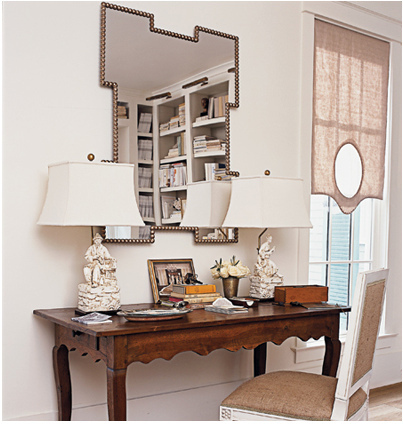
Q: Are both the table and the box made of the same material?
A: Yes, both the table and the box are made of wood.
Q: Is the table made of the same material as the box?
A: Yes, both the table and the box are made of wood.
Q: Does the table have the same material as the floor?
A: Yes, both the table and the floor are made of wood.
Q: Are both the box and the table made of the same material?
A: Yes, both the box and the table are made of wood.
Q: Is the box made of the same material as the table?
A: Yes, both the box and the table are made of wood.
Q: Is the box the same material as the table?
A: Yes, both the box and the table are made of wood.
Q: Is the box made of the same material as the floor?
A: Yes, both the box and the floor are made of wood.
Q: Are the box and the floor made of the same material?
A: Yes, both the box and the floor are made of wood.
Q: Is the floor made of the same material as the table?
A: Yes, both the floor and the table are made of wood.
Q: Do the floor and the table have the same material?
A: Yes, both the floor and the table are made of wood.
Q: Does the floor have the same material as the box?
A: Yes, both the floor and the box are made of wood.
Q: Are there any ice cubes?
A: No, there are no ice cubes.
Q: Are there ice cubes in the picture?
A: No, there are no ice cubes.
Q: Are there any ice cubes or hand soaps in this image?
A: No, there are no ice cubes or hand soaps.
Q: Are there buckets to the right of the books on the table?
A: Yes, there is a bucket to the right of the books.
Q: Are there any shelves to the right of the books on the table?
A: No, there is a bucket to the right of the books.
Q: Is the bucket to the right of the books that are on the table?
A: Yes, the bucket is to the right of the books.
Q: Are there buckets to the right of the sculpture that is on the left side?
A: Yes, there is a bucket to the right of the sculpture.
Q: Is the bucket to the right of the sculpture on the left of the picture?
A: Yes, the bucket is to the right of the sculpture.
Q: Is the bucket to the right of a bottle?
A: No, the bucket is to the right of the sculpture.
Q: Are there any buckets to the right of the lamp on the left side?
A: Yes, there is a bucket to the right of the lamp.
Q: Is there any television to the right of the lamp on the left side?
A: No, there is a bucket to the right of the lamp.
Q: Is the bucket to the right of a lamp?
A: Yes, the bucket is to the right of a lamp.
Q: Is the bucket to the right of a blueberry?
A: No, the bucket is to the right of a lamp.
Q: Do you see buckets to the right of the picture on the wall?
A: Yes, there is a bucket to the right of the picture.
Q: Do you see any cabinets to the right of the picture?
A: No, there is a bucket to the right of the picture.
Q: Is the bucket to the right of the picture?
A: Yes, the bucket is to the right of the picture.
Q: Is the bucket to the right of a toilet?
A: No, the bucket is to the right of the picture.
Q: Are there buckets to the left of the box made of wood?
A: Yes, there is a bucket to the left of the box.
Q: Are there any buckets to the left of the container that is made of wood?
A: Yes, there is a bucket to the left of the box.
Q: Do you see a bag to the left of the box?
A: No, there is a bucket to the left of the box.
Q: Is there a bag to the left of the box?
A: No, there is a bucket to the left of the box.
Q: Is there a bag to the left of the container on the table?
A: No, there is a bucket to the left of the box.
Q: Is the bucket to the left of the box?
A: Yes, the bucket is to the left of the box.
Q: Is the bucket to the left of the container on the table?
A: Yes, the bucket is to the left of the box.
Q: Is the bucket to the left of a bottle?
A: No, the bucket is to the left of the box.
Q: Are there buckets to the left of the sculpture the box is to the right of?
A: Yes, there is a bucket to the left of the sculpture.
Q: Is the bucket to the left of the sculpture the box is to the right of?
A: Yes, the bucket is to the left of the sculpture.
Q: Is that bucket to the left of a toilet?
A: No, the bucket is to the left of the sculpture.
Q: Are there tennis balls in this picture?
A: No, there are no tennis balls.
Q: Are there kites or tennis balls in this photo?
A: No, there are no tennis balls or kites.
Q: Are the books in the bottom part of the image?
A: Yes, the books are in the bottom of the image.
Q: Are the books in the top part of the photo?
A: No, the books are in the bottom of the image.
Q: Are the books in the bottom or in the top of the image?
A: The books are in the bottom of the image.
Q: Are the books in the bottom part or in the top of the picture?
A: The books are in the bottom of the image.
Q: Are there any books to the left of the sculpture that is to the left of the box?
A: Yes, there are books to the left of the sculpture.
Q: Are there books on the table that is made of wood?
A: Yes, there are books on the table.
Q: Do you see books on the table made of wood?
A: Yes, there are books on the table.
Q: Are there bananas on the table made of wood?
A: No, there are books on the table.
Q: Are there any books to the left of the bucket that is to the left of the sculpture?
A: Yes, there are books to the left of the bucket.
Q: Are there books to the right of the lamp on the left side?
A: Yes, there are books to the right of the lamp.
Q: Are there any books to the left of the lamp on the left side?
A: No, the books are to the right of the lamp.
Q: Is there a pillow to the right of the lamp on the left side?
A: No, there are books to the right of the lamp.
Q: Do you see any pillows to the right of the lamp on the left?
A: No, there are books to the right of the lamp.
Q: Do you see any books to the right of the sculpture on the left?
A: Yes, there are books to the right of the sculpture.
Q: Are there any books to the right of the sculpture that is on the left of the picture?
A: Yes, there are books to the right of the sculpture.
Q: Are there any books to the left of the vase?
A: Yes, there are books to the left of the vase.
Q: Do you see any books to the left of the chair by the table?
A: Yes, there are books to the left of the chair.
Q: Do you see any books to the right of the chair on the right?
A: No, the books are to the left of the chair.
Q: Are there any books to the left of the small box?
A: Yes, there are books to the left of the box.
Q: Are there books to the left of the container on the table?
A: Yes, there are books to the left of the box.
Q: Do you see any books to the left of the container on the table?
A: Yes, there are books to the left of the box.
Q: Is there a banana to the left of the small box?
A: No, there are books to the left of the box.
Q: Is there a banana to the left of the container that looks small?
A: No, there are books to the left of the box.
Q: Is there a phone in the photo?
A: No, there are no phones.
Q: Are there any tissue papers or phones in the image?
A: No, there are no phones or tissue papers.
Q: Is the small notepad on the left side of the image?
A: Yes, the notepad is on the left of the image.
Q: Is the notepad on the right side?
A: No, the notepad is on the left of the image.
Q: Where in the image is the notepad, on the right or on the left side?
A: The notepad is on the left of the image.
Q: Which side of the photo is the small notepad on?
A: The notepad is on the left of the image.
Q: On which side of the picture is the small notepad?
A: The notepad is on the left of the image.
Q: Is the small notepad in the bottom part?
A: Yes, the notepad is in the bottom of the image.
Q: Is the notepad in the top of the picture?
A: No, the notepad is in the bottom of the image.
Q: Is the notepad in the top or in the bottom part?
A: The notepad is in the bottom of the image.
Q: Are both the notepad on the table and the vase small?
A: Yes, both the notepad and the vase are small.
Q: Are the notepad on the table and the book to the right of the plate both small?
A: Yes, both the notepad and the book are small.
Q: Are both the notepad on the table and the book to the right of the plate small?
A: Yes, both the notepad and the book are small.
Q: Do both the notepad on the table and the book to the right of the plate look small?
A: Yes, both the notepad and the book are small.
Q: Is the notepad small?
A: Yes, the notepad is small.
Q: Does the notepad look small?
A: Yes, the notepad is small.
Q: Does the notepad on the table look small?
A: Yes, the notepad is small.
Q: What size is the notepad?
A: The notepad is small.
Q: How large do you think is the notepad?
A: The notepad is small.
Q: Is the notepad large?
A: No, the notepad is small.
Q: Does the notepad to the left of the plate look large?
A: No, the notepad is small.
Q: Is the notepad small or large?
A: The notepad is small.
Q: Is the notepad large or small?
A: The notepad is small.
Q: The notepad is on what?
A: The notepad is on the table.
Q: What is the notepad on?
A: The notepad is on the table.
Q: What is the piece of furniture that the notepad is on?
A: The piece of furniture is a table.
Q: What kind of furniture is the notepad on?
A: The notepad is on the table.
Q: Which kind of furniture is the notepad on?
A: The notepad is on the table.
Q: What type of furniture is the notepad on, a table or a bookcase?
A: The notepad is on a table.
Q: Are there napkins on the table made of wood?
A: No, there is a notepad on the table.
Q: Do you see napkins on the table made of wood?
A: No, there is a notepad on the table.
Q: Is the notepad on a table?
A: Yes, the notepad is on a table.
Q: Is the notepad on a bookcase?
A: No, the notepad is on a table.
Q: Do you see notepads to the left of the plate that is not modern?
A: Yes, there is a notepad to the left of the plate.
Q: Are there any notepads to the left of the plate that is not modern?
A: Yes, there is a notepad to the left of the plate.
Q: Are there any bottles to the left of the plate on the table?
A: No, there is a notepad to the left of the plate.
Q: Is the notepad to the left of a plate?
A: Yes, the notepad is to the left of a plate.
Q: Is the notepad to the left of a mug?
A: No, the notepad is to the left of a plate.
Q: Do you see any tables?
A: Yes, there is a table.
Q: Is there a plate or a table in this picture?
A: Yes, there is a table.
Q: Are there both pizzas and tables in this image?
A: No, there is a table but no pizzas.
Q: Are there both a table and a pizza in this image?
A: No, there is a table but no pizzas.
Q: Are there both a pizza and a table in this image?
A: No, there is a table but no pizzas.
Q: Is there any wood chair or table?
A: Yes, there is a wood table.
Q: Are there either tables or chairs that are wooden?
A: Yes, the table is wooden.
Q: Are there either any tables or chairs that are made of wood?
A: Yes, the table is made of wood.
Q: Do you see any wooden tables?
A: Yes, there is a wood table.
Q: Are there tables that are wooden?
A: Yes, there is a table that is wooden.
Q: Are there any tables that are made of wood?
A: Yes, there is a table that is made of wood.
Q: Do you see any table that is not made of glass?
A: Yes, there is a table that is made of wood.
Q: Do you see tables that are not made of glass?
A: Yes, there is a table that is made of wood.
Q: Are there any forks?
A: No, there are no forks.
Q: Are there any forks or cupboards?
A: No, there are no forks or cupboards.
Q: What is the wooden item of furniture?
A: The piece of furniture is a table.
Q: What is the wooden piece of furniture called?
A: The piece of furniture is a table.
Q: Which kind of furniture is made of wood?
A: The furniture is a table.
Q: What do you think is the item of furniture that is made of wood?
A: The piece of furniture is a table.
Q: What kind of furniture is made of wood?
A: The furniture is a table.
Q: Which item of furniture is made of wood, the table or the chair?
A: The table is made of wood.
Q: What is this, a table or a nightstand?
A: This is a table.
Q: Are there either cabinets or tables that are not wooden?
A: No, there is a table but it is wooden.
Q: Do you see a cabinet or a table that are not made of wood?
A: No, there is a table but it is made of wood.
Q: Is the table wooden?
A: Yes, the table is wooden.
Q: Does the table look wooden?
A: Yes, the table is wooden.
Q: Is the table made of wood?
A: Yes, the table is made of wood.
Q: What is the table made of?
A: The table is made of wood.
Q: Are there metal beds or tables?
A: No, there is a table but it is wooden.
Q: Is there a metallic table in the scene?
A: No, there is a table but it is wooden.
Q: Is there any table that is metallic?
A: No, there is a table but it is wooden.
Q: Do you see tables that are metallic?
A: No, there is a table but it is wooden.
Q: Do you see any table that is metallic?
A: No, there is a table but it is wooden.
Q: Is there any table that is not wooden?
A: No, there is a table but it is wooden.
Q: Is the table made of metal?
A: No, the table is made of wood.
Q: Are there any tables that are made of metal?
A: No, there is a table but it is made of wood.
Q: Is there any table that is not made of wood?
A: No, there is a table but it is made of wood.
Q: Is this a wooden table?
A: Yes, this is a wooden table.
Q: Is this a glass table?
A: No, this is a wooden table.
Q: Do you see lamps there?
A: Yes, there is a lamp.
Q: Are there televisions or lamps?
A: Yes, there is a lamp.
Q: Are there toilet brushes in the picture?
A: No, there are no toilet brushes.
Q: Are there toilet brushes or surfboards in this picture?
A: No, there are no toilet brushes or surfboards.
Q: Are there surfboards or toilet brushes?
A: No, there are no toilet brushes or surfboards.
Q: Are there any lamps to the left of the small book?
A: Yes, there is a lamp to the left of the book.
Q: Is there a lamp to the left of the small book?
A: Yes, there is a lamp to the left of the book.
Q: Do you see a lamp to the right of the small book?
A: No, the lamp is to the left of the book.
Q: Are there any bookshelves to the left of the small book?
A: No, there is a lamp to the left of the book.